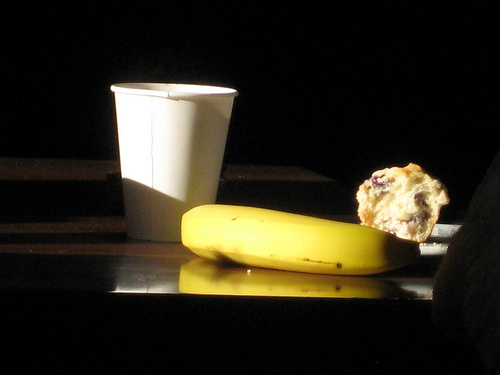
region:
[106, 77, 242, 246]
a white paper cup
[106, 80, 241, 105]
the mouth of the cup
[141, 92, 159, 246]
the white seam on the cup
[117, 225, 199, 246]
the base of the cup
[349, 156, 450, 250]
a muffin on the plate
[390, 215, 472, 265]
a plate on the table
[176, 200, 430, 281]
a yellow banana on the table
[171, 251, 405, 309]
a reflection on the table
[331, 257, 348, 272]
a brown spot on the banana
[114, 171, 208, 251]
a shadow on the cup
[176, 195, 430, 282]
a banana on the table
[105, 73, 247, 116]
the mouth of a cup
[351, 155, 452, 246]
a muffin on the table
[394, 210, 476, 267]
a plate under the muffin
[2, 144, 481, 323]
a table under the food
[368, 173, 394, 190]
a fruit in the muffin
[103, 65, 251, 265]
A cup is on the table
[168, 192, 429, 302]
A banana is on the table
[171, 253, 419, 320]
Banana's reflection is on the table's surface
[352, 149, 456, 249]
A muffin in the background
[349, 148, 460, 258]
Muffin is eaten into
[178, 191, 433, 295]
Banana is yellow in color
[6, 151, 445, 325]
Table is dark brown in color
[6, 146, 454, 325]
Table is made of wood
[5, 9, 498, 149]
Background of the image is black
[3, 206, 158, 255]
Cup is casting a shadow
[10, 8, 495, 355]
a snack is sitting on the table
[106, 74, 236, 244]
a white cup is sitting on the table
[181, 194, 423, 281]
a banana is on the table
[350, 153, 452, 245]
a muffin is on the table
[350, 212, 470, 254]
the muffin is on a plate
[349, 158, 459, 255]
the blueberry muffin is on the plate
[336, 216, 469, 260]
the plate is white on the table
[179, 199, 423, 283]
the banana still has to be peeled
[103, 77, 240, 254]
the cup is disposible paper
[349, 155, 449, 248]
the muffin is half eaten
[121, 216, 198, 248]
the base of a cup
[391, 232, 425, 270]
the stem of a banana